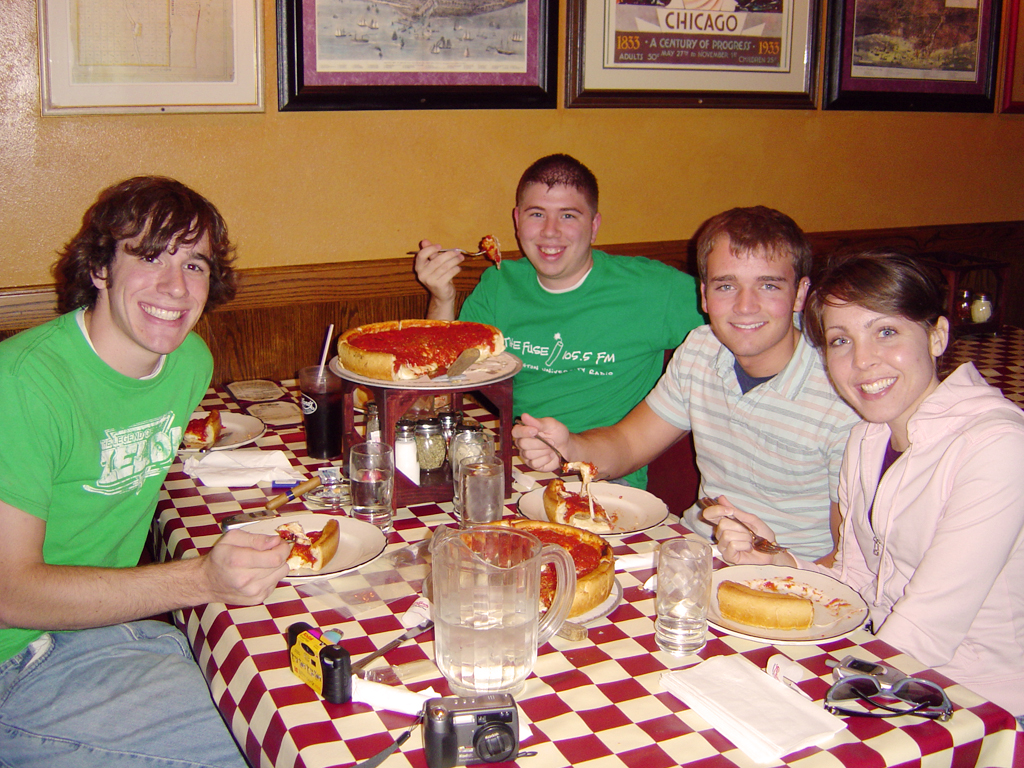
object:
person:
[800, 237, 1024, 719]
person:
[512, 204, 863, 590]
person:
[416, 152, 707, 492]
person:
[0, 177, 296, 761]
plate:
[180, 411, 267, 450]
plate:
[228, 513, 389, 582]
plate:
[517, 481, 670, 547]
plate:
[703, 562, 870, 646]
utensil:
[695, 495, 788, 555]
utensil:
[406, 248, 497, 256]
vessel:
[654, 536, 712, 657]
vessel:
[350, 445, 396, 532]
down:
[0, 616, 246, 768]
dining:
[142, 379, 1024, 767]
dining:
[249, 595, 364, 768]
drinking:
[429, 525, 576, 699]